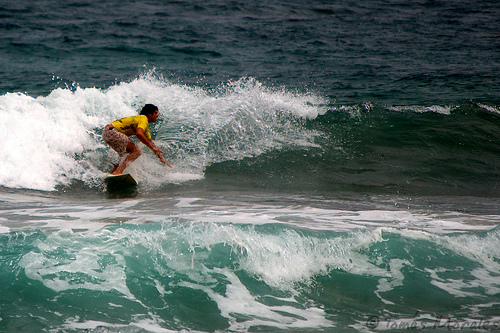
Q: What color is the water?
A: Green.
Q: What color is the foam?
A: White.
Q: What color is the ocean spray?
A: White.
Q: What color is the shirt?
A: Yellow.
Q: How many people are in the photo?
A: 1.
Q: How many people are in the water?
A: One.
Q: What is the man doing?
A: Surfing.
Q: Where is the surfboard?
A: By the white foam.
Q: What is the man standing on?
A: A surfboard.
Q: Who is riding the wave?
A: A man.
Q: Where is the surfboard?
A: The ocean.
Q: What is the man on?
A: A surfboard.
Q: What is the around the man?
A: Water.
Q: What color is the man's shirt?
A: Yellow.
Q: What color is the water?
A: White and blue.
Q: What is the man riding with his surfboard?
A: A wave.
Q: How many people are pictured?
A: One.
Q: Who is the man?
A: A surfer.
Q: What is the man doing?
A: He's surfing.